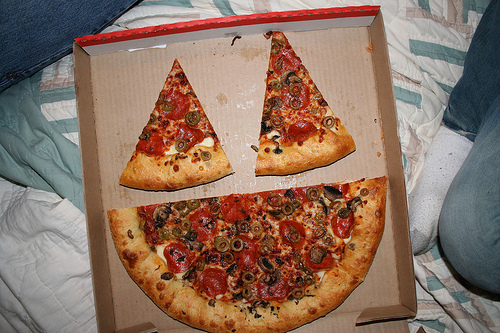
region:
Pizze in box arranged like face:
[98, 23, 463, 329]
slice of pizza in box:
[132, 59, 224, 176]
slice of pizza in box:
[271, 35, 366, 171]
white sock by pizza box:
[409, 108, 494, 250]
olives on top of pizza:
[209, 237, 244, 253]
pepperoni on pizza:
[211, 195, 263, 223]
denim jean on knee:
[421, 160, 496, 250]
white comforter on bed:
[29, 25, 494, 271]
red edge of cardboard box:
[69, 9, 403, 68]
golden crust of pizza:
[139, 222, 299, 328]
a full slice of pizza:
[103, 47, 235, 189]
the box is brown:
[368, 280, 400, 311]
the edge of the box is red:
[210, 15, 257, 23]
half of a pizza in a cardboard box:
[108, 179, 404, 331]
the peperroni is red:
[164, 242, 195, 265]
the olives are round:
[205, 228, 245, 258]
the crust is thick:
[353, 196, 381, 246]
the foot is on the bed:
[412, 126, 470, 253]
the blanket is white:
[15, 246, 67, 302]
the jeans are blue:
[22, 13, 59, 41]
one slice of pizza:
[146, 63, 231, 180]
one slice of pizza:
[257, 41, 359, 174]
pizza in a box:
[82, 23, 433, 312]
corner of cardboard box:
[65, 37, 136, 94]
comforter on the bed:
[10, 171, 77, 281]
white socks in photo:
[410, 107, 462, 260]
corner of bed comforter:
[428, 270, 473, 320]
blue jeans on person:
[20, 13, 60, 58]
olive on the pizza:
[167, 134, 188, 154]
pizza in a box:
[122, 35, 385, 320]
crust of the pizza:
[258, 133, 357, 181]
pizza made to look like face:
[113, 28, 388, 327]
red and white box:
[101, 18, 175, 84]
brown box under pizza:
[218, 59, 255, 106]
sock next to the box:
[388, 122, 480, 257]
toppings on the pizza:
[163, 187, 348, 298]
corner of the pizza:
[358, 160, 395, 208]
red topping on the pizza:
[211, 190, 256, 240]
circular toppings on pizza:
[213, 233, 241, 258]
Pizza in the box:
[63, 18, 430, 329]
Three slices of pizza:
[98, 30, 395, 330]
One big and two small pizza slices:
[107, 33, 404, 332]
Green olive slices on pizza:
[213, 233, 247, 256]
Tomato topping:
[279, 217, 335, 274]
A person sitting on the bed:
[409, 1, 494, 268]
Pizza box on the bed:
[63, 15, 429, 330]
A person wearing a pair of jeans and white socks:
[401, 3, 496, 260]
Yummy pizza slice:
[123, 53, 242, 192]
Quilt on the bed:
[15, 0, 480, 280]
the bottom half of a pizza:
[107, 173, 391, 332]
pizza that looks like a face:
[107, 32, 387, 332]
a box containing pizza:
[75, 7, 415, 332]